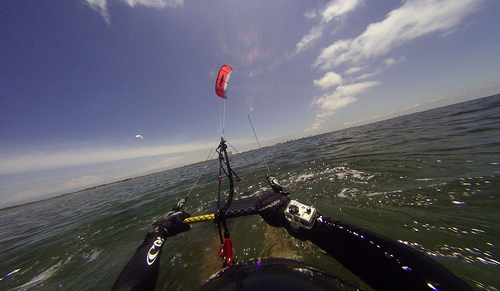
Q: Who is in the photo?
A: A person kitesurfing.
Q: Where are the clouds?
A: In sky.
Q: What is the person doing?
A: Surfing.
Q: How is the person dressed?
A: In a wetsuit.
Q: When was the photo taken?
A: During kitesurfing.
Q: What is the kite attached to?
A: Ropes.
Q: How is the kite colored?
A: Orange.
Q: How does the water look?
A: Green.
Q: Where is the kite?
A: Up in the sky.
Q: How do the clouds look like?
A: White.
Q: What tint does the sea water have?
A: Green tint.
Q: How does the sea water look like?
A: Wavy.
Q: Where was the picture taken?
A: Over water.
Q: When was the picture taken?
A: Daytime.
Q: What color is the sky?
A: Blue.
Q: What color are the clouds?
A: White.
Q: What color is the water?
A: Green.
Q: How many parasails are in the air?
A: Two.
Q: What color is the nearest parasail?
A: Red.